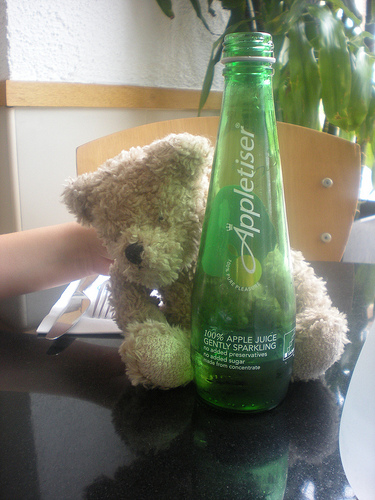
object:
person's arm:
[0, 222, 78, 298]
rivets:
[321, 233, 332, 243]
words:
[203, 330, 276, 370]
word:
[234, 125, 260, 273]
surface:
[172, 410, 269, 476]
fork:
[92, 278, 110, 317]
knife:
[45, 273, 99, 340]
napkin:
[36, 275, 123, 335]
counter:
[0, 260, 375, 498]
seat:
[76, 117, 361, 263]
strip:
[0, 79, 223, 109]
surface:
[294, 418, 326, 482]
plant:
[156, 0, 375, 195]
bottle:
[190, 32, 295, 416]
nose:
[125, 242, 144, 265]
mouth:
[139, 265, 142, 270]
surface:
[0, 400, 38, 499]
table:
[0, 261, 375, 500]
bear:
[60, 133, 352, 390]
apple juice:
[190, 345, 293, 412]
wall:
[0, 0, 287, 91]